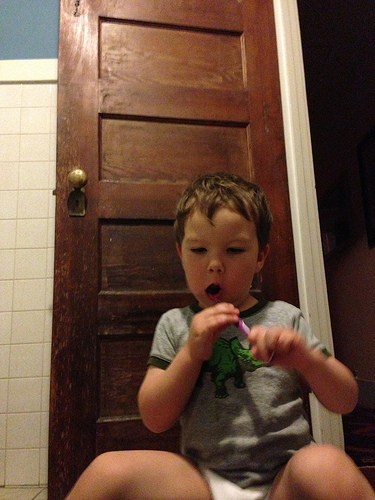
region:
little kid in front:
[82, 157, 333, 398]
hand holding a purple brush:
[232, 289, 286, 346]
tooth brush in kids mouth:
[162, 261, 270, 399]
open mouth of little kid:
[115, 158, 266, 356]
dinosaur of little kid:
[146, 315, 279, 395]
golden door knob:
[54, 152, 115, 219]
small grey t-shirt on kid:
[65, 293, 325, 447]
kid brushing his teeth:
[58, 158, 308, 445]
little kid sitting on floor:
[139, 172, 330, 489]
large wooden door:
[12, 12, 285, 243]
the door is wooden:
[25, 21, 365, 490]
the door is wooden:
[47, 39, 266, 287]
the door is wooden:
[18, 91, 199, 358]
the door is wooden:
[51, 107, 278, 408]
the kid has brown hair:
[166, 169, 274, 265]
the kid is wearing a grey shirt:
[146, 291, 335, 480]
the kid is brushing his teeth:
[205, 289, 271, 367]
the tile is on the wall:
[0, 75, 64, 486]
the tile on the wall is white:
[0, 75, 60, 488]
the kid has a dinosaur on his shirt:
[176, 325, 276, 404]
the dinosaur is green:
[181, 326, 274, 399]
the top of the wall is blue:
[0, 0, 64, 65]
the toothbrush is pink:
[209, 289, 258, 341]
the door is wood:
[44, 1, 315, 499]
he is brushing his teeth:
[218, 276, 266, 363]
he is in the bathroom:
[42, 168, 366, 413]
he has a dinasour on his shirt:
[217, 348, 266, 411]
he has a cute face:
[191, 222, 244, 301]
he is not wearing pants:
[195, 467, 303, 490]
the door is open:
[64, 161, 143, 314]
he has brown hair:
[193, 183, 266, 217]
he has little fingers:
[200, 309, 241, 338]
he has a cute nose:
[210, 252, 233, 278]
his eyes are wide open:
[177, 231, 257, 258]